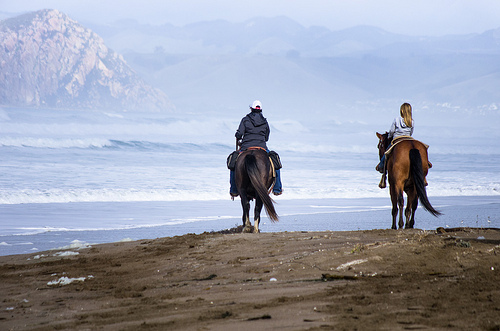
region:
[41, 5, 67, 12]
tip of a hill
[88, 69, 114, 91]
section of a hill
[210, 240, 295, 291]
edge of a shore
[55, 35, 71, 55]
part of a mountain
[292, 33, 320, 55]
section of a hill terrain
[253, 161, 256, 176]
tail of a horse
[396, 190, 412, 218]
back leg of a horse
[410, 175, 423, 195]
tail of a black horse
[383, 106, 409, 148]
a small girl on a horse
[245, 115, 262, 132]
back of a man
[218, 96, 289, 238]
a man riding a black horse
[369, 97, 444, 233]
a woman riding a brown horse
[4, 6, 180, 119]
a rocky mountain in the distance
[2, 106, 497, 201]
crashing waves in the distance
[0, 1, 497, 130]
mountains in the distance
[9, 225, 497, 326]
a muddy hilltop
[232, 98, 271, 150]
a mean wearing a cap and winter jacket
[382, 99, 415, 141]
a woman wearing a grey hoodie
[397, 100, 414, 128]
a woman's long blonde hair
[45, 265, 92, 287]
a small patch of white snow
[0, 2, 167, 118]
Mountains in the background.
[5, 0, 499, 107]
The background is foggy.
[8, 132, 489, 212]
The water is blue.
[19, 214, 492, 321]
the dirt is brown.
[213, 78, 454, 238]
Two people on horses.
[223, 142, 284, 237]
The horse is black.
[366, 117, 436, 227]
The horse is brown.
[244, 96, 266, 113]
the man is wearing a hat.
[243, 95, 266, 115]
The hat is white.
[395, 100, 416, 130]
The girl is blonde.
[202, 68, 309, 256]
a man on horse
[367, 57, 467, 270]
a lady on a horse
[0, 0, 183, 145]
a snow covered mountain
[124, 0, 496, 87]
a snowy mountain range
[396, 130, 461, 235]
a black horse tail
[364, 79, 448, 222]
a woman with blond hair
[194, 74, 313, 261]
a man wearing a white hat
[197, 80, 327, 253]
a man wearing a dark blue coat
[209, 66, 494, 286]
two horses being ridden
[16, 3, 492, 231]
a mountainous landscape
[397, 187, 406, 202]
back leg of a horse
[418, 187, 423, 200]
tail of a brown horse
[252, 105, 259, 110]
section of a white cap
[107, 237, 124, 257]
edge of an ocean shore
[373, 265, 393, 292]
section of a rocky landscape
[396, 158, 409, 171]
back of a brown horse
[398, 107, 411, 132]
little girl on a horse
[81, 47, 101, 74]
section of a snowy mountain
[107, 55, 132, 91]
section of a hilly terrrain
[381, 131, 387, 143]
head of a horse